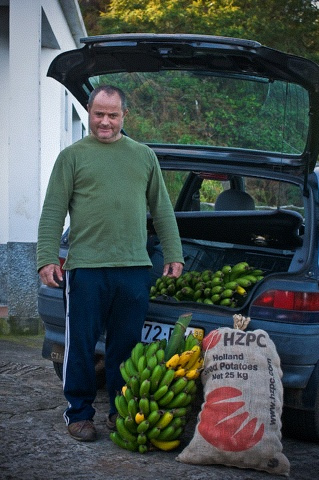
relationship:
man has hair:
[34, 84, 185, 444] [87, 85, 126, 115]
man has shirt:
[34, 84, 185, 444] [34, 136, 185, 270]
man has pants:
[34, 84, 185, 444] [61, 265, 152, 425]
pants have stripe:
[61, 265, 152, 425] [62, 270, 73, 427]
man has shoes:
[34, 84, 185, 444] [66, 414, 119, 442]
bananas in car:
[149, 253, 265, 309] [38, 32, 319, 441]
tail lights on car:
[252, 288, 318, 325] [38, 32, 319, 441]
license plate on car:
[140, 320, 205, 350] [38, 32, 319, 441]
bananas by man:
[113, 312, 206, 455] [34, 84, 185, 444]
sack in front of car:
[175, 314, 293, 478] [38, 32, 319, 441]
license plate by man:
[140, 320, 205, 350] [34, 84, 185, 444]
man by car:
[34, 84, 185, 444] [38, 32, 319, 441]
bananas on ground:
[113, 312, 206, 455] [1, 335, 317, 478]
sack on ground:
[175, 314, 293, 478] [1, 335, 317, 478]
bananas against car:
[113, 312, 206, 455] [38, 32, 319, 441]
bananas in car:
[113, 312, 206, 455] [38, 32, 319, 441]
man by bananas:
[34, 84, 185, 444] [113, 312, 206, 455]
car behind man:
[38, 32, 319, 441] [34, 84, 185, 444]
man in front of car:
[34, 84, 185, 444] [38, 32, 319, 441]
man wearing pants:
[34, 84, 185, 444] [61, 265, 152, 425]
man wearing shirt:
[34, 84, 185, 444] [34, 136, 185, 270]